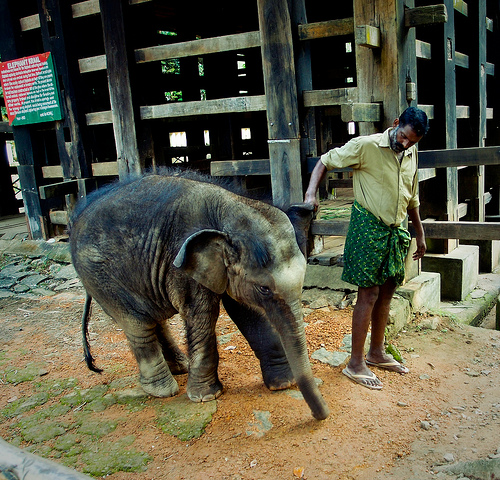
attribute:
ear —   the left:
[162, 222, 242, 309]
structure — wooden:
[2, 0, 498, 298]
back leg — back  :
[124, 320, 177, 411]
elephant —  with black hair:
[48, 163, 396, 473]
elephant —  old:
[63, 152, 342, 435]